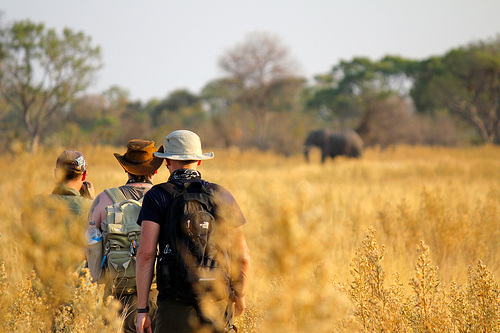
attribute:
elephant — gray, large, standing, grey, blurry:
[305, 127, 367, 165]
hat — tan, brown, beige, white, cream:
[161, 131, 214, 164]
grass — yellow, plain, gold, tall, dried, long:
[296, 166, 485, 313]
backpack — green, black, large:
[168, 198, 234, 303]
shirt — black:
[149, 185, 247, 305]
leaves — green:
[451, 59, 494, 81]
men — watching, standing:
[58, 141, 255, 324]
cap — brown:
[120, 141, 163, 175]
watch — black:
[135, 305, 152, 315]